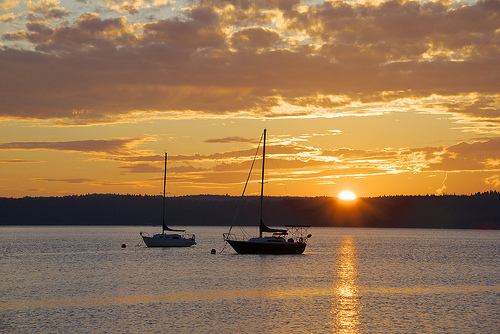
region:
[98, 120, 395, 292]
two boats on water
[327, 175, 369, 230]
sun is setting behind mountains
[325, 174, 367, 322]
sun is reflecting in water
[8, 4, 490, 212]
orange and pink clouds in sky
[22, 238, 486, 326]
reflection from sun makes cross in water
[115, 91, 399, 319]
two boats next to each other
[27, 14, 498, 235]
partly cloudy sky in photo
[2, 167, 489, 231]
mountains in background of photo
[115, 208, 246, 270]
two buoys in water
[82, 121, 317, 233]
no sails on boats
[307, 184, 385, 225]
The sun as it is setting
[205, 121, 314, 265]
The taller of the two boats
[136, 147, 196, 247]
The shorter of the two boats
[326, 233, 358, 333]
The sun reflected on the water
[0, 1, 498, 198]
The clouds in the sky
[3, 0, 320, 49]
The blue sky seen between the clouds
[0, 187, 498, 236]
The black hill at the edge of the water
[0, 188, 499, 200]
The horizon line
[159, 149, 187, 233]
The shorter mast on the left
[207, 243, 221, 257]
The buoy in front of the boat on the right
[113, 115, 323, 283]
two sailboats on the water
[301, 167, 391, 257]
sun partially obscured behind trees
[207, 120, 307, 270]
sailboat with the sail down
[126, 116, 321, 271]
large sailboat and smaller sailboat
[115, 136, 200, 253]
sailboat that's anchored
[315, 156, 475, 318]
sun reflecting off the water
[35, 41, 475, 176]
clouds in the sky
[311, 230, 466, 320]
calm water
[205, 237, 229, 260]
bouy in the water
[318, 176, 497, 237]
trees at the edge of the water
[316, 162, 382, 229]
a beautiful orange sunset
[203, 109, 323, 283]
a small sailing boat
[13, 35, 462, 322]
two boats at sunset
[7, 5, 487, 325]
sailboats in the water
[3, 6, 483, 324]
sailboats drifting at sunrise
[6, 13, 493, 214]
sunset on a cloudy day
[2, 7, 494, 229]
sunrise over the mountains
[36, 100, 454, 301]
sailboats drifting at evening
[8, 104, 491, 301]
boats sailing after sunset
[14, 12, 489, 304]
sailboats under a bright orange sunset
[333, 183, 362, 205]
sun slowly going down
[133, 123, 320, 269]
two tiny boats on the water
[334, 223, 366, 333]
sunlight reflecting on the water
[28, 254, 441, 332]
water with many ripples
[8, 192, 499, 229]
many trees lining the shore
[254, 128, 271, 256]
long, tall, skinny rod sticking out of the boat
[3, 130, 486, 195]
orange sky with sporadic clouds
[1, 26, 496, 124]
long and thick cloud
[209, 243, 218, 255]
buoy floating in the water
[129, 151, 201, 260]
boat